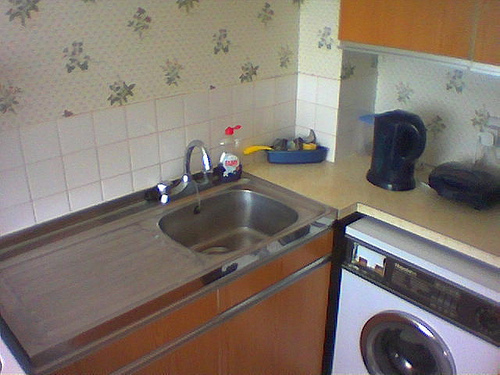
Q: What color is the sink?
A: Silver.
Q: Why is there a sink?
A: To wash.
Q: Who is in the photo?
A: No one.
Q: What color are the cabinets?
A: Brown.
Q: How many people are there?
A: None.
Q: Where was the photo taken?
A: In the kitchen of a home.